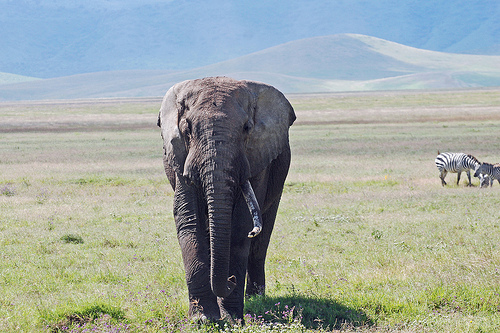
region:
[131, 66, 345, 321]
an elephant missing a tusk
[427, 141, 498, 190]
zebras grazing on grass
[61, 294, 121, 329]
a clump of green grass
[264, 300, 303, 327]
tiny purple flowers in the ground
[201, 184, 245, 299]
a long gray trunk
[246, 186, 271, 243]
an old white tusk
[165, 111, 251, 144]
eyes in a head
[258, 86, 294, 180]
big floppy gray ear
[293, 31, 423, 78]
a large sand dune in the distance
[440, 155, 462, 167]
black stripes on a zebra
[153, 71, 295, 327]
an elephant is walking on the savannah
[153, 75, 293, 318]
the elephant has only one tusk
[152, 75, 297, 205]
the elephant has large ears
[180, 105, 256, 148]
the elephant's eyes are open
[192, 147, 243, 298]
the trunk of the elephant is curled upward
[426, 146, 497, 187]
two zebras are together on the plain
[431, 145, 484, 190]
the zebra has black and white stripes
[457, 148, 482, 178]
the zebra has a black mane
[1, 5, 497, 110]
rolling mountains are on the horizon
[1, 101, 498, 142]
a wandering river going through the plain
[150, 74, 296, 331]
an elephant with a missing tusk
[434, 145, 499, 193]
zebras grazing in the background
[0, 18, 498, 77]
hill in the distance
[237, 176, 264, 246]
an elephant tusk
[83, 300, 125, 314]
green grass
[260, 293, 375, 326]
the shadow cast by an elephant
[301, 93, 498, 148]
a large expanse of open land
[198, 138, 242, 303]
the trunk of an elephant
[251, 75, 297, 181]
the left ear of an elephant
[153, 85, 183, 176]
a the right ear of an elephant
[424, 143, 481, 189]
Black and white zebra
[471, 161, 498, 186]
Black and white zebra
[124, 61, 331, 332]
Large elephant with one tusk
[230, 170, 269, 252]
Dirty white elephant tusk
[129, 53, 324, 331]
Large elephant standing in a field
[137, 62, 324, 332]
Grey elephant walking through the grass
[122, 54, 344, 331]
Large elephant with only one tusk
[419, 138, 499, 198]
Group of zebras standing in the grass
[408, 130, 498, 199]
Two zebras standing near each other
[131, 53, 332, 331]
Large elephant walking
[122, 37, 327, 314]
the elephant is gray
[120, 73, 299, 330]
the elephant is wrinkled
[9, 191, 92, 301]
the grass is green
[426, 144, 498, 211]
the zebra is eating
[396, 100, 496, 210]
two zebras in the field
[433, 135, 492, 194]
the zebras are stripes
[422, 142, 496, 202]
the zebras are black and white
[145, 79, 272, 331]
the elephant has trunk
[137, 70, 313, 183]
the elephant has two ears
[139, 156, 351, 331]
the elephant is walking